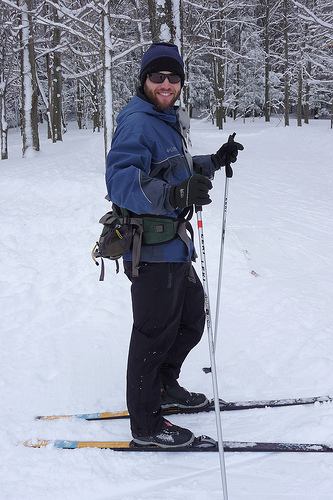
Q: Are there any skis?
A: Yes, there are skis.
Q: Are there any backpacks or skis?
A: Yes, there are skis.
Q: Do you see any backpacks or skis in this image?
A: Yes, there are skis.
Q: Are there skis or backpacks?
A: Yes, there are skis.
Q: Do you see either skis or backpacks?
A: Yes, there are skis.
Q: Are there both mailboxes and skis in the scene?
A: No, there are skis but no mailboxes.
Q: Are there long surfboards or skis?
A: Yes, there are long skis.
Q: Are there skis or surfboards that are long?
A: Yes, the skis are long.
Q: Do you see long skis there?
A: Yes, there are long skis.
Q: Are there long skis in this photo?
A: Yes, there are long skis.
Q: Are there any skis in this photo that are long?
A: Yes, there are skis that are long.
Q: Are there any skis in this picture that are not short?
A: Yes, there are long skis.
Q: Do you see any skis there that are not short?
A: Yes, there are long skis.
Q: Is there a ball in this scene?
A: No, there are no balls.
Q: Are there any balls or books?
A: No, there are no balls or books.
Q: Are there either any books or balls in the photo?
A: No, there are no balls or books.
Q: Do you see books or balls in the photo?
A: No, there are no balls or books.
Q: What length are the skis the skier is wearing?
A: The skis are long.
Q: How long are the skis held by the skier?
A: The skis are long.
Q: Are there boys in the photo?
A: No, there are no boys.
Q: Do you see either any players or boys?
A: No, there are no boys or players.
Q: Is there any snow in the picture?
A: Yes, there is snow.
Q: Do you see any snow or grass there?
A: Yes, there is snow.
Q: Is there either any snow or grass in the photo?
A: Yes, there is snow.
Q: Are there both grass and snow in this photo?
A: No, there is snow but no grass.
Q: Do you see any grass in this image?
A: No, there is no grass.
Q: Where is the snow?
A: The snow is on the ground.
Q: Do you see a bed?
A: No, there are no beds.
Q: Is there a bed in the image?
A: No, there are no beds.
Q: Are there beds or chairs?
A: No, there are no beds or chairs.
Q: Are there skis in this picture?
A: Yes, there are skis.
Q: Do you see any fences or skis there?
A: Yes, there are skis.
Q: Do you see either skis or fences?
A: Yes, there are skis.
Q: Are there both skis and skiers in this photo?
A: Yes, there are both skis and a skier.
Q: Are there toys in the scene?
A: No, there are no toys.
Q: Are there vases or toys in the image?
A: No, there are no toys or vases.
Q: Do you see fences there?
A: No, there are no fences.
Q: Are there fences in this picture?
A: No, there are no fences.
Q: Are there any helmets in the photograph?
A: No, there are no helmets.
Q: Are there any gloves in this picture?
A: Yes, there are gloves.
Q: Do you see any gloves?
A: Yes, there are gloves.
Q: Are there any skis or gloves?
A: Yes, there are gloves.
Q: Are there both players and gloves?
A: No, there are gloves but no players.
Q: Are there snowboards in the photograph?
A: No, there are no snowboards.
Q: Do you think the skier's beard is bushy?
A: Yes, the beard is bushy.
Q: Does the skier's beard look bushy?
A: Yes, the beard is bushy.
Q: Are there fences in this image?
A: No, there are no fences.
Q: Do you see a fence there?
A: No, there are no fences.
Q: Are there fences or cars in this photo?
A: No, there are no fences or cars.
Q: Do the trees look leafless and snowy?
A: Yes, the trees are leafless and snowy.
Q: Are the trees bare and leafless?
A: No, the trees are leafless but snowy.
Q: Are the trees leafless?
A: Yes, the trees are leafless.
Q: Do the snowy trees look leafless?
A: Yes, the trees are leafless.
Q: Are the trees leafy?
A: No, the trees are leafless.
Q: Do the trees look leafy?
A: No, the trees are leafless.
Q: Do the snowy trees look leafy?
A: No, the trees are leafless.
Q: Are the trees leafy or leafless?
A: The trees are leafless.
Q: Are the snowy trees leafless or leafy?
A: The trees are leafless.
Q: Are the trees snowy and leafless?
A: Yes, the trees are snowy and leafless.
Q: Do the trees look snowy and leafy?
A: No, the trees are snowy but leafless.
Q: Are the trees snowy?
A: Yes, the trees are snowy.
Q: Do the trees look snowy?
A: Yes, the trees are snowy.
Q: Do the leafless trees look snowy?
A: Yes, the trees are snowy.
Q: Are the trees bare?
A: No, the trees are snowy.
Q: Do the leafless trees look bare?
A: No, the trees are snowy.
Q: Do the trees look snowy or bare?
A: The trees are snowy.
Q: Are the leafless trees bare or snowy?
A: The trees are snowy.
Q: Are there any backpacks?
A: No, there are no backpacks.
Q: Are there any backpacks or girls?
A: No, there are no backpacks or girls.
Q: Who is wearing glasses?
A: The skier is wearing glasses.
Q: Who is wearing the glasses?
A: The skier is wearing glasses.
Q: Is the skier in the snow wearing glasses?
A: Yes, the skier is wearing glasses.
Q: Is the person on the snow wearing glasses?
A: Yes, the skier is wearing glasses.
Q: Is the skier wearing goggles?
A: No, the skier is wearing glasses.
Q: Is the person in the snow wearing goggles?
A: No, the skier is wearing glasses.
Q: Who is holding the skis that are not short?
A: The skier is holding the skis.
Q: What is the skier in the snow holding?
A: The skier is holding the skis.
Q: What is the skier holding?
A: The skier is holding the skis.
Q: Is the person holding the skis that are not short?
A: Yes, the skier is holding the skis.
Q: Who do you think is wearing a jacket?
A: The skier is wearing a jacket.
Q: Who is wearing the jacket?
A: The skier is wearing a jacket.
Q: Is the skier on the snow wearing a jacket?
A: Yes, the skier is wearing a jacket.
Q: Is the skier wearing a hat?
A: No, the skier is wearing a jacket.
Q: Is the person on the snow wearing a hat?
A: No, the skier is wearing a jacket.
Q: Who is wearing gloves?
A: The skier is wearing gloves.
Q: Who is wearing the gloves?
A: The skier is wearing gloves.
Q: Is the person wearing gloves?
A: Yes, the skier is wearing gloves.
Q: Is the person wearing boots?
A: No, the skier is wearing gloves.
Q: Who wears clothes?
A: The skier wears clothes.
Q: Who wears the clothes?
A: The skier wears clothes.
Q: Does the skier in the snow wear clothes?
A: Yes, the skier wears clothes.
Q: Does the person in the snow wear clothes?
A: Yes, the skier wears clothes.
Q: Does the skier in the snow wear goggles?
A: No, the skier wears clothes.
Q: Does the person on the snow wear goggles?
A: No, the skier wears clothes.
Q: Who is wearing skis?
A: The skier is wearing skis.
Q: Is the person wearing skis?
A: Yes, the skier is wearing skis.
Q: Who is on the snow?
A: The skier is on the snow.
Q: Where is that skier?
A: The skier is on the snow.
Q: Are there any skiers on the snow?
A: Yes, there is a skier on the snow.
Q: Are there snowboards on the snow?
A: No, there is a skier on the snow.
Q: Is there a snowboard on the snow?
A: No, there is a skier on the snow.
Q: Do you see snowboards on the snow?
A: No, there is a skier on the snow.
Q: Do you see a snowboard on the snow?
A: No, there is a skier on the snow.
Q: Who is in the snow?
A: The skier is in the snow.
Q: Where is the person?
A: The skier is in the snow.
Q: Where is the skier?
A: The skier is in the snow.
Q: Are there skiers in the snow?
A: Yes, there is a skier in the snow.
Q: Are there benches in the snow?
A: No, there is a skier in the snow.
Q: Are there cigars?
A: No, there are no cigars.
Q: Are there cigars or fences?
A: No, there are no cigars or fences.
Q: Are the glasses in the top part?
A: Yes, the glasses are in the top of the image.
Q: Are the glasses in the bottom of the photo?
A: No, the glasses are in the top of the image.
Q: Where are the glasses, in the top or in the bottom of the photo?
A: The glasses are in the top of the image.